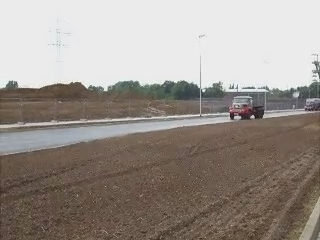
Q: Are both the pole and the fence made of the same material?
A: Yes, both the pole and the fence are made of metal.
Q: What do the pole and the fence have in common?
A: The material, both the pole and the fence are metallic.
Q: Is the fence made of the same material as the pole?
A: Yes, both the fence and the pole are made of metal.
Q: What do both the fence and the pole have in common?
A: The material, both the fence and the pole are metallic.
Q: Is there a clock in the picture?
A: No, there are no clocks.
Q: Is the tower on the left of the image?
A: Yes, the tower is on the left of the image.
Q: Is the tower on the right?
A: No, the tower is on the left of the image.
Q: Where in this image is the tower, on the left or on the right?
A: The tower is on the left of the image.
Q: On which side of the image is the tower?
A: The tower is on the left of the image.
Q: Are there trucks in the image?
A: Yes, there is a truck.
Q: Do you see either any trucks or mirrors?
A: Yes, there is a truck.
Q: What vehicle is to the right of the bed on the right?
A: The vehicle is a truck.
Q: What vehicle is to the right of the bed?
A: The vehicle is a truck.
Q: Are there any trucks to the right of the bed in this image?
A: Yes, there is a truck to the right of the bed.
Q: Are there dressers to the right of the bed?
A: No, there is a truck to the right of the bed.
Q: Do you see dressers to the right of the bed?
A: No, there is a truck to the right of the bed.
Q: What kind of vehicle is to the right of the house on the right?
A: The vehicle is a truck.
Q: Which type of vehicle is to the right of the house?
A: The vehicle is a truck.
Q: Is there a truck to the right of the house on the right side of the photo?
A: Yes, there is a truck to the right of the house.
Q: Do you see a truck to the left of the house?
A: No, the truck is to the right of the house.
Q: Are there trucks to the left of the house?
A: No, the truck is to the right of the house.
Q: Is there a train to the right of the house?
A: No, there is a truck to the right of the house.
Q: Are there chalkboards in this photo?
A: No, there are no chalkboards.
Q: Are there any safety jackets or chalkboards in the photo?
A: No, there are no chalkboards or safety jackets.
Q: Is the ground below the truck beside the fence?
A: Yes, the ground is below the truck.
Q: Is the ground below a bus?
A: No, the ground is below the truck.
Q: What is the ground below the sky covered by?
A: The ground is covered by the dirt.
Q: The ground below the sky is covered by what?
A: The ground is covered by the dirt.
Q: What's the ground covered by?
A: The ground is covered by the dirt.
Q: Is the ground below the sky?
A: Yes, the ground is below the sky.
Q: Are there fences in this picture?
A: Yes, there is a fence.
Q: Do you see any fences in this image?
A: Yes, there is a fence.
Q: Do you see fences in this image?
A: Yes, there is a fence.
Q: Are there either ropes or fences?
A: Yes, there is a fence.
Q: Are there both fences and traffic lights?
A: No, there is a fence but no traffic lights.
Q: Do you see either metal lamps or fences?
A: Yes, there is a metal fence.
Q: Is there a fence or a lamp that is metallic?
A: Yes, the fence is metallic.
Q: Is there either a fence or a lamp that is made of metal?
A: Yes, the fence is made of metal.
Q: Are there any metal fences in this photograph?
A: Yes, there is a metal fence.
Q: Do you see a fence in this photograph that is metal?
A: Yes, there is a metal fence.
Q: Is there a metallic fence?
A: Yes, there is a metal fence.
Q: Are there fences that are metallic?
A: Yes, there is a fence that is metallic.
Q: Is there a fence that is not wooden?
A: Yes, there is a metallic fence.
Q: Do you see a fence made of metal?
A: Yes, there is a fence that is made of metal.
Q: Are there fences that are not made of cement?
A: Yes, there is a fence that is made of metal.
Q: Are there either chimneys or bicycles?
A: No, there are no chimneys or bicycles.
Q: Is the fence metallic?
A: Yes, the fence is metallic.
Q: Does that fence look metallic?
A: Yes, the fence is metallic.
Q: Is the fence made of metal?
A: Yes, the fence is made of metal.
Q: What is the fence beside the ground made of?
A: The fence is made of metal.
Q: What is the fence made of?
A: The fence is made of metal.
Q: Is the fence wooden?
A: No, the fence is metallic.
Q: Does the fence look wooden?
A: No, the fence is metallic.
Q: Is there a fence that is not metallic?
A: No, there is a fence but it is metallic.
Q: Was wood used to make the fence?
A: No, the fence is made of metal.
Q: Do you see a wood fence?
A: No, there is a fence but it is made of metal.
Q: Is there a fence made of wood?
A: No, there is a fence but it is made of metal.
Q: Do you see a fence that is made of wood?
A: No, there is a fence but it is made of metal.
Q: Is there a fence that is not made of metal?
A: No, there is a fence but it is made of metal.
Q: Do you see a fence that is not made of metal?
A: No, there is a fence but it is made of metal.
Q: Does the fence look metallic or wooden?
A: The fence is metallic.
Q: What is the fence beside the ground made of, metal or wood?
A: The fence is made of metal.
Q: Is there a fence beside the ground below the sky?
A: Yes, there is a fence beside the ground.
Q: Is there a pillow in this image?
A: No, there are no pillows.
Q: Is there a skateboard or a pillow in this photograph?
A: No, there are no pillows or skateboards.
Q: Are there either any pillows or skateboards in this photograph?
A: No, there are no pillows or skateboards.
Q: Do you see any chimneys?
A: No, there are no chimneys.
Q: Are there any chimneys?
A: No, there are no chimneys.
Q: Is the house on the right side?
A: Yes, the house is on the right of the image.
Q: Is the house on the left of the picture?
A: No, the house is on the right of the image.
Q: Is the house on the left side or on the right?
A: The house is on the right of the image.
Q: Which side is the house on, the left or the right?
A: The house is on the right of the image.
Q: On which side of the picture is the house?
A: The house is on the right of the image.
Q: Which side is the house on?
A: The house is on the right of the image.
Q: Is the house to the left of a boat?
A: No, the house is to the left of the truck.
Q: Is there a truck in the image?
A: Yes, there is a truck.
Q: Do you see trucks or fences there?
A: Yes, there is a truck.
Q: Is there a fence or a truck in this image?
A: Yes, there is a truck.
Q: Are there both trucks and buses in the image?
A: No, there is a truck but no buses.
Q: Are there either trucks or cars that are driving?
A: Yes, the truck is driving.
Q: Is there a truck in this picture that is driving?
A: Yes, there is a truck that is driving.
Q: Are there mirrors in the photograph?
A: No, there are no mirrors.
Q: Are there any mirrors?
A: No, there are no mirrors.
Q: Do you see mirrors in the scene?
A: No, there are no mirrors.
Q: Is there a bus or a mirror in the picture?
A: No, there are no mirrors or buses.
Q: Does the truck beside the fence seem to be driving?
A: Yes, the truck is driving.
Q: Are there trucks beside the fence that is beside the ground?
A: Yes, there is a truck beside the fence.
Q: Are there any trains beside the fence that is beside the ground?
A: No, there is a truck beside the fence.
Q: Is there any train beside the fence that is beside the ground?
A: No, there is a truck beside the fence.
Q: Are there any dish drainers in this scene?
A: No, there are no dish drainers.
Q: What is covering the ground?
A: The dirt is covering the ground.